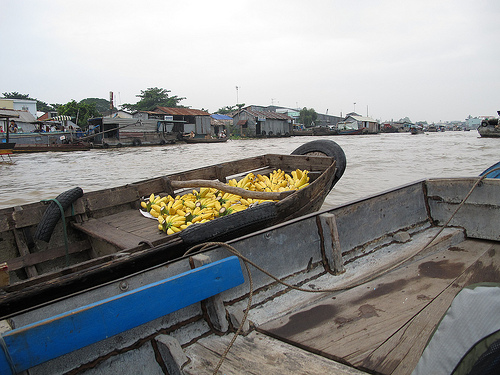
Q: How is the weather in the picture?
A: It is cloudy.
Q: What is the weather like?
A: It is cloudy.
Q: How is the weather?
A: It is cloudy.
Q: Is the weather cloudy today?
A: Yes, it is cloudy.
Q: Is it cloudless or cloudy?
A: It is cloudy.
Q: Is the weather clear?
A: No, it is cloudy.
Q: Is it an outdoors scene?
A: Yes, it is outdoors.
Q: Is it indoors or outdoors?
A: It is outdoors.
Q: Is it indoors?
A: No, it is outdoors.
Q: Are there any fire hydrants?
A: No, there are no fire hydrants.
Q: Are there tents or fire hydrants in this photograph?
A: No, there are no fire hydrants or tents.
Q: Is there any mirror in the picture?
A: No, there are no mirrors.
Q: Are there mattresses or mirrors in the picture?
A: No, there are no mirrors or mattresses.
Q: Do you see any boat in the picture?
A: Yes, there is a boat.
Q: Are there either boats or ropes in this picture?
A: Yes, there is a boat.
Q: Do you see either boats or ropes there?
A: Yes, there is a boat.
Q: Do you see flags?
A: No, there are no flags.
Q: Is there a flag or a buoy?
A: No, there are no flags or buoys.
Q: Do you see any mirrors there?
A: No, there are no mirrors.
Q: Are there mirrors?
A: No, there are no mirrors.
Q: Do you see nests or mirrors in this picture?
A: No, there are no mirrors or nests.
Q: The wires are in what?
A: The wires are in the boat.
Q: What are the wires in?
A: The wires are in the boat.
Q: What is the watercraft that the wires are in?
A: The watercraft is a boat.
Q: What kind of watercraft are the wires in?
A: The wires are in the boat.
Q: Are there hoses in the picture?
A: No, there are no hoses.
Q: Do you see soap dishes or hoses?
A: No, there are no hoses or soap dishes.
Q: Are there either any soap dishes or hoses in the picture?
A: No, there are no hoses or soap dishes.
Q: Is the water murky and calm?
A: Yes, the water is murky and calm.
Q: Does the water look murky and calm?
A: Yes, the water is murky and calm.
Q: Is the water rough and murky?
A: No, the water is murky but calm.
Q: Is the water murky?
A: Yes, the water is murky.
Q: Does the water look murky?
A: Yes, the water is murky.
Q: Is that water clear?
A: No, the water is murky.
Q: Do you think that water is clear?
A: No, the water is murky.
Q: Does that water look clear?
A: No, the water is murky.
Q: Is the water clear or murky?
A: The water is murky.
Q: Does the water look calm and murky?
A: Yes, the water is calm and murky.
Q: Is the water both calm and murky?
A: Yes, the water is calm and murky.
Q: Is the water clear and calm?
A: No, the water is calm but murky.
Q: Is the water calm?
A: Yes, the water is calm.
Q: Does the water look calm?
A: Yes, the water is calm.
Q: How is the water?
A: The water is calm.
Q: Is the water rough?
A: No, the water is calm.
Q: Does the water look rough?
A: No, the water is calm.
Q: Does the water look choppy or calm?
A: The water is calm.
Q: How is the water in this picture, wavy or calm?
A: The water is calm.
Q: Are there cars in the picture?
A: No, there are no cars.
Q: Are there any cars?
A: No, there are no cars.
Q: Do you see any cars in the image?
A: No, there are no cars.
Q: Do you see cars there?
A: No, there are no cars.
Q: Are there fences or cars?
A: No, there are no cars or fences.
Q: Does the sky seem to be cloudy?
A: Yes, the sky is cloudy.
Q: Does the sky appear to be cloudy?
A: Yes, the sky is cloudy.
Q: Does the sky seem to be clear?
A: No, the sky is cloudy.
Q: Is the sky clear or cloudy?
A: The sky is cloudy.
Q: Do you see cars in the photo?
A: No, there are no cars.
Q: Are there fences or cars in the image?
A: No, there are no cars or fences.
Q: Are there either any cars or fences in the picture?
A: No, there are no cars or fences.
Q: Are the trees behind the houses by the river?
A: Yes, the trees are behind the houses.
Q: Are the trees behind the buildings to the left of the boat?
A: Yes, the trees are behind the houses.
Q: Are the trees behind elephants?
A: No, the trees are behind the houses.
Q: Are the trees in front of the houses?
A: No, the trees are behind the houses.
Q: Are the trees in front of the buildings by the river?
A: No, the trees are behind the houses.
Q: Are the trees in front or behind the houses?
A: The trees are behind the houses.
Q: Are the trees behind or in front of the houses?
A: The trees are behind the houses.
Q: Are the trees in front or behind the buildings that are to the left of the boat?
A: The trees are behind the houses.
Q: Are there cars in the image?
A: No, there are no cars.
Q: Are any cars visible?
A: No, there are no cars.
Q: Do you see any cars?
A: No, there are no cars.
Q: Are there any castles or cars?
A: No, there are no cars or castles.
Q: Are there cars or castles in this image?
A: No, there are no cars or castles.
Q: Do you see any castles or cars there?
A: No, there are no cars or castles.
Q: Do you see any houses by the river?
A: Yes, there are houses by the river.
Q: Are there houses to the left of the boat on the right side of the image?
A: Yes, there are houses to the left of the boat.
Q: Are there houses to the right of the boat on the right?
A: No, the houses are to the left of the boat.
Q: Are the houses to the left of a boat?
A: Yes, the houses are to the left of a boat.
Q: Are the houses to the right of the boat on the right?
A: No, the houses are to the left of the boat.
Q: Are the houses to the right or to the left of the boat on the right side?
A: The houses are to the left of the boat.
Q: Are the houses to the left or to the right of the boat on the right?
A: The houses are to the left of the boat.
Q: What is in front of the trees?
A: The houses are in front of the trees.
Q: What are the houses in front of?
A: The houses are in front of the trees.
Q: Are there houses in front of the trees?
A: Yes, there are houses in front of the trees.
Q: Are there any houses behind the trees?
A: No, the houses are in front of the trees.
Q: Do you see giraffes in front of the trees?
A: No, there are houses in front of the trees.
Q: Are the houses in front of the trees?
A: Yes, the houses are in front of the trees.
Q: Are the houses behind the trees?
A: No, the houses are in front of the trees.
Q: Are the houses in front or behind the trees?
A: The houses are in front of the trees.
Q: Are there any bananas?
A: Yes, there are bananas.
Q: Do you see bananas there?
A: Yes, there are bananas.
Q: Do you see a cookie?
A: No, there are no cookies.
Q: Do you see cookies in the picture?
A: No, there are no cookies.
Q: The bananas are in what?
A: The bananas are in the boat.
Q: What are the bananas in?
A: The bananas are in the boat.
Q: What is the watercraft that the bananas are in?
A: The watercraft is a boat.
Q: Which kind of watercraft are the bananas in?
A: The bananas are in the boat.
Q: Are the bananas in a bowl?
A: No, the bananas are in the boat.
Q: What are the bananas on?
A: The bananas are on the boat.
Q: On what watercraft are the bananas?
A: The bananas are on the boat.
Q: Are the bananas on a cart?
A: No, the bananas are on the boat.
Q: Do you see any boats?
A: Yes, there is a boat.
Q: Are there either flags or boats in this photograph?
A: Yes, there is a boat.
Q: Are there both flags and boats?
A: No, there is a boat but no flags.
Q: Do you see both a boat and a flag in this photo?
A: No, there is a boat but no flags.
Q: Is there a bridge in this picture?
A: No, there are no bridges.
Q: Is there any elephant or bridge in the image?
A: No, there are no bridges or elephants.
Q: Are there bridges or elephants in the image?
A: No, there are no bridges or elephants.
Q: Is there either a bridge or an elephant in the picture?
A: No, there are no bridges or elephants.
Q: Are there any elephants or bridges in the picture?
A: No, there are no bridges or elephants.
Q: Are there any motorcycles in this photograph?
A: No, there are no motorcycles.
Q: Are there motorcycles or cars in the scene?
A: No, there are no motorcycles or cars.